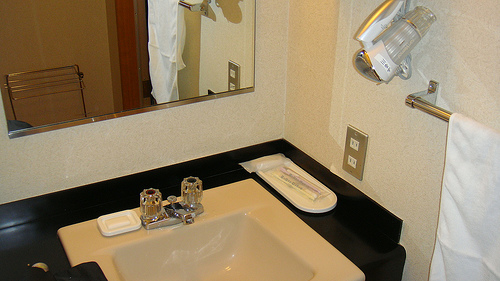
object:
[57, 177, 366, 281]
sink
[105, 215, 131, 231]
soap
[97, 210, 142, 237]
soap dish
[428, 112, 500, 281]
towel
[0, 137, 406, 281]
counter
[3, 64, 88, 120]
luggage rack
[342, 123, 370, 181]
outlet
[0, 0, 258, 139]
mirror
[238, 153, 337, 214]
toiletries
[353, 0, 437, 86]
hairdryer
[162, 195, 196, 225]
faucet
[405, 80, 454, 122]
rack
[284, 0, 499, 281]
wall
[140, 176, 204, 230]
water fixture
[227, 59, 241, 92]
outlet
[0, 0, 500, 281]
bathroom